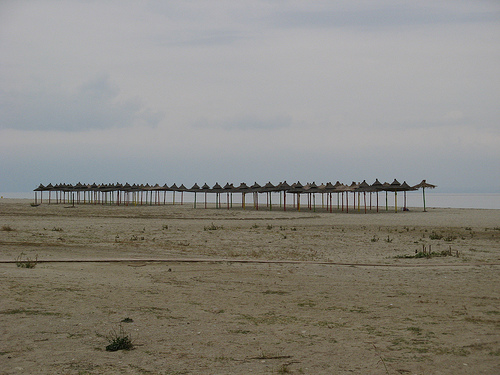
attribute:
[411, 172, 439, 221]
beach umbrella — thatched 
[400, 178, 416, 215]
beach umbrella — thatched 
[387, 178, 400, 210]
beach umbrella — thatched 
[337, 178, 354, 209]
beach umbrella — thatched 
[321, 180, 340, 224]
beach umbrella — thatched 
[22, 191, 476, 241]
beach — long, brown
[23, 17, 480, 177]
sky — gray, cloudy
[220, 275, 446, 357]
area — grassy, sandy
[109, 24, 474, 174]
cloud — dark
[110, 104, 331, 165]
cloud — dark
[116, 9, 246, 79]
cloud — dark